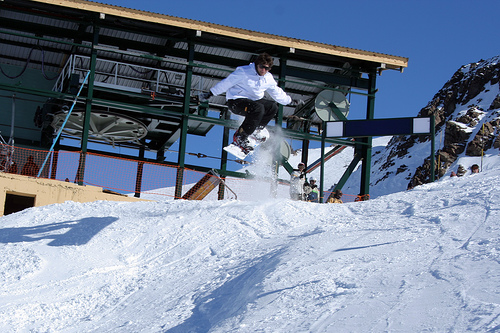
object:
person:
[199, 54, 306, 154]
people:
[455, 164, 463, 177]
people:
[468, 163, 480, 175]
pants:
[226, 97, 281, 138]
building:
[0, 0, 409, 217]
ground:
[0, 168, 500, 333]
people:
[449, 171, 455, 177]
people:
[306, 177, 318, 203]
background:
[2, 0, 500, 332]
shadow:
[1, 216, 119, 246]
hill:
[0, 56, 500, 331]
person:
[326, 190, 345, 203]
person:
[289, 162, 305, 201]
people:
[20, 154, 40, 178]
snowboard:
[222, 127, 269, 160]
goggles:
[257, 65, 271, 70]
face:
[256, 62, 271, 74]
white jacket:
[210, 63, 292, 106]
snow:
[0, 134, 500, 332]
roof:
[2, 0, 410, 125]